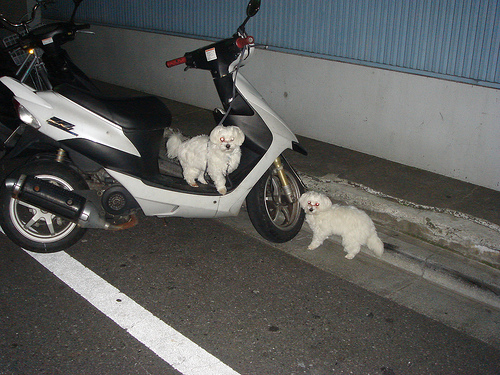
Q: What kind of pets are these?
A: Dogs.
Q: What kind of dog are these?
A: Poodle.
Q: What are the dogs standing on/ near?
A: Motorcycle.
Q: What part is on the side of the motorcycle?
A: Exhaust pipe.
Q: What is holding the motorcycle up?
A: Wheels.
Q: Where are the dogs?
A: Parking lot.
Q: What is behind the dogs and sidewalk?
A: Blue building.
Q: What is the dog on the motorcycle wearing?
A: Harness.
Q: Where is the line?
A: On the ground.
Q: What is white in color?
A: The dog.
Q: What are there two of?
A: Dogs.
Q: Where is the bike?
A: On the ground.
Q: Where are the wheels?
A: On the bike.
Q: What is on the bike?
A: A seat.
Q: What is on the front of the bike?
A: Handlebars.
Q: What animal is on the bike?
A: Dog.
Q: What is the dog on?
A: Bike.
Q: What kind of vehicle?
A: Scooter.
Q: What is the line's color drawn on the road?
A: White.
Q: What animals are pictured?
A: Two small dogs.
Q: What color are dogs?
A: White.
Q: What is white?
A: A motorbike.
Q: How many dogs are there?
A: Two.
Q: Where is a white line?
A: On the ground.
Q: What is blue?
A: Side of a building.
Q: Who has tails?
A: The dogs.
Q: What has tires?
A: A motorbike.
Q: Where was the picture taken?
A: On a curb.